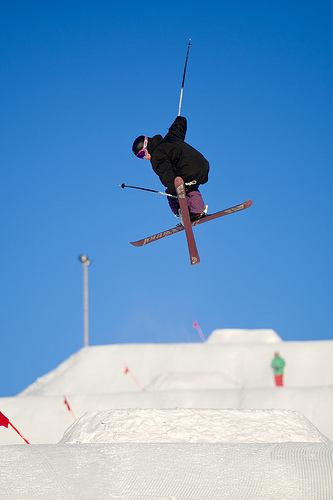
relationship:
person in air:
[130, 118, 208, 225] [76, 43, 132, 96]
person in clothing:
[269, 348, 288, 387] [262, 343, 308, 380]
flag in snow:
[0, 394, 33, 455] [56, 433, 206, 494]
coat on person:
[148, 132, 250, 211] [122, 119, 243, 237]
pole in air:
[159, 13, 235, 136] [21, 106, 87, 179]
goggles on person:
[134, 146, 146, 160] [109, 80, 246, 225]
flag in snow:
[0, 411, 9, 428] [93, 429, 135, 496]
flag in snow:
[0, 411, 9, 428] [37, 441, 104, 479]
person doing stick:
[130, 118, 208, 225] [119, 182, 178, 200]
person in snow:
[269, 348, 288, 387] [266, 335, 297, 409]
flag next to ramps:
[0, 411, 9, 428] [81, 388, 306, 493]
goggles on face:
[106, 130, 162, 163] [122, 126, 163, 159]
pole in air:
[83, 254, 95, 346] [41, 30, 111, 124]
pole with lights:
[70, 243, 101, 368] [76, 230, 99, 270]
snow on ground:
[62, 405, 322, 444] [0, 326, 319, 497]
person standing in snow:
[269, 348, 288, 387] [1, 326, 322, 498]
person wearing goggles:
[130, 118, 208, 225] [134, 135, 149, 160]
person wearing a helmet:
[130, 118, 208, 225] [131, 133, 149, 154]